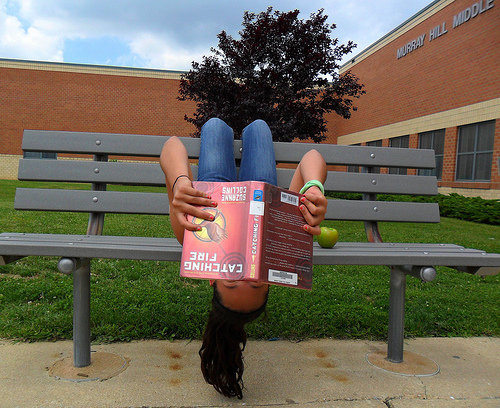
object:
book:
[177, 175, 321, 290]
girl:
[150, 114, 335, 408]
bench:
[0, 124, 500, 287]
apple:
[314, 224, 341, 251]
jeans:
[194, 115, 282, 187]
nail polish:
[300, 205, 306, 213]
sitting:
[145, 111, 336, 408]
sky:
[0, 0, 428, 67]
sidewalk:
[1, 335, 500, 408]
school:
[322, 0, 500, 222]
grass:
[0, 179, 500, 345]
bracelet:
[296, 178, 327, 195]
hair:
[195, 277, 274, 407]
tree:
[167, 0, 375, 160]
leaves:
[251, 87, 265, 98]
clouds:
[0, 0, 92, 64]